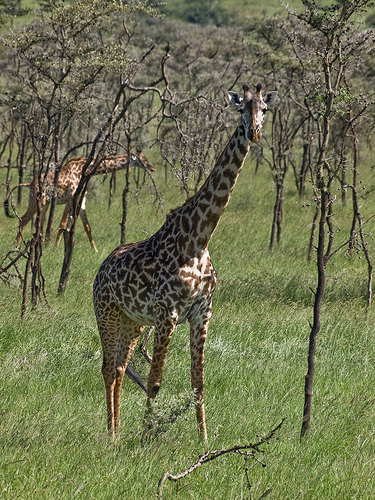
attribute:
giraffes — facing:
[2, 80, 278, 453]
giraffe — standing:
[93, 84, 277, 443]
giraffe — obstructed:
[4, 148, 151, 253]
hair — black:
[3, 199, 16, 220]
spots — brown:
[172, 226, 202, 268]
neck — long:
[187, 123, 252, 263]